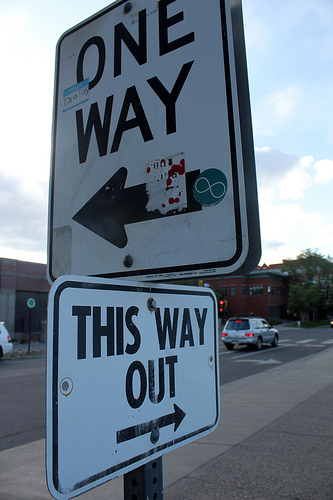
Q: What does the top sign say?
A: One Way.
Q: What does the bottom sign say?
A: This Way Out.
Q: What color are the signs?
A: White and Black.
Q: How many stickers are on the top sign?
A: 3.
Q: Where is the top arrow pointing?
A: Left.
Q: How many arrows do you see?
A: 3.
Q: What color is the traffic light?
A: Red.